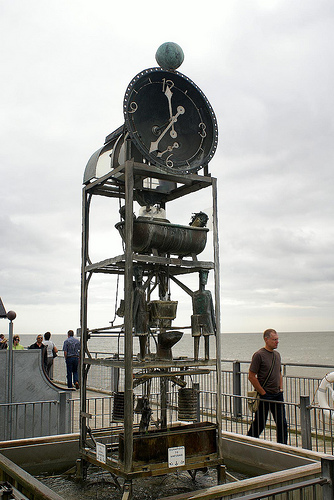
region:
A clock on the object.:
[127, 73, 233, 159]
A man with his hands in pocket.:
[243, 374, 297, 399]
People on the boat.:
[26, 331, 89, 386]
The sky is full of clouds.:
[225, 177, 331, 308]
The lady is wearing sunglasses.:
[11, 333, 22, 342]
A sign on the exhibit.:
[150, 438, 202, 473]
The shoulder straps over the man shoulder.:
[259, 351, 283, 381]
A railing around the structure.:
[210, 382, 311, 448]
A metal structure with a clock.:
[91, 55, 239, 378]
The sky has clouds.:
[31, 16, 236, 87]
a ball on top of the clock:
[130, 33, 203, 87]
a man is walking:
[236, 317, 301, 438]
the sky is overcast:
[195, 219, 330, 318]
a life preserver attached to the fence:
[301, 366, 331, 413]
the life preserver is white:
[308, 358, 330, 422]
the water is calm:
[284, 325, 325, 358]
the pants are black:
[245, 388, 297, 435]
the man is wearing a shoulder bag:
[223, 340, 287, 411]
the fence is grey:
[232, 378, 327, 450]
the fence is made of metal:
[238, 379, 331, 440]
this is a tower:
[137, 376, 187, 491]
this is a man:
[246, 351, 263, 419]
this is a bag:
[236, 351, 256, 434]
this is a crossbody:
[233, 395, 265, 432]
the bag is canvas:
[240, 362, 274, 480]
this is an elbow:
[244, 364, 262, 407]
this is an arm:
[232, 363, 266, 412]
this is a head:
[270, 329, 281, 375]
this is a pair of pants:
[239, 407, 283, 468]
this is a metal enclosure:
[42, 410, 52, 437]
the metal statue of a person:
[130, 261, 152, 359]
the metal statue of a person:
[191, 266, 216, 363]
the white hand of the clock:
[145, 107, 190, 160]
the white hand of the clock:
[163, 84, 179, 139]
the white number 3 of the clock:
[198, 120, 206, 138]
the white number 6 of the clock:
[165, 152, 174, 166]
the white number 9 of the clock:
[127, 98, 138, 111]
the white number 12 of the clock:
[160, 76, 175, 95]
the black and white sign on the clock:
[95, 438, 106, 465]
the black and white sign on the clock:
[167, 445, 186, 467]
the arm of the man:
[247, 350, 267, 394]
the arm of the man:
[277, 350, 284, 391]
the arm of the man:
[62, 338, 69, 357]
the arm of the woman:
[50, 341, 57, 355]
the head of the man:
[263, 327, 278, 348]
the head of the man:
[66, 328, 73, 336]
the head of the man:
[35, 333, 44, 343]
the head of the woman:
[43, 330, 50, 340]